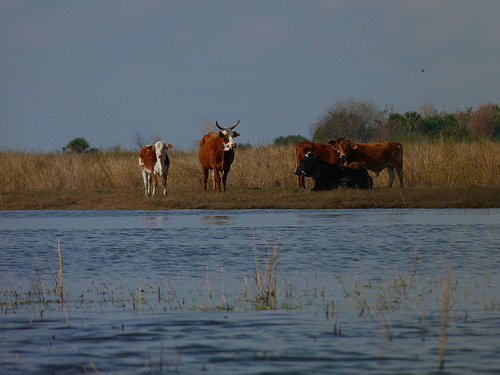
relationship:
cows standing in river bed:
[122, 112, 411, 196] [38, 175, 482, 206]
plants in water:
[130, 243, 465, 318] [35, 219, 462, 276]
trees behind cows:
[296, 93, 493, 149] [120, 111, 435, 207]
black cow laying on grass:
[296, 147, 375, 188] [13, 134, 498, 197]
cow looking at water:
[198, 120, 240, 189] [4, 210, 440, 371]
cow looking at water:
[137, 134, 196, 194] [4, 210, 440, 371]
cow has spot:
[198, 120, 240, 189] [218, 128, 228, 142]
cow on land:
[137, 134, 196, 194] [7, 141, 499, 203]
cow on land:
[198, 120, 240, 189] [7, 141, 499, 203]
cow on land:
[330, 131, 409, 199] [7, 141, 499, 203]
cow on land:
[279, 138, 339, 188] [7, 141, 499, 203]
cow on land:
[318, 165, 378, 193] [7, 141, 499, 203]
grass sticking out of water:
[4, 223, 495, 342] [20, 208, 483, 363]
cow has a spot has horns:
[196, 115, 250, 194] [214, 117, 242, 131]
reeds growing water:
[267, 130, 470, 184] [20, 239, 468, 361]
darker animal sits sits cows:
[295, 150, 376, 191] [293, 124, 417, 194]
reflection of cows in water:
[141, 204, 415, 237] [92, 201, 347, 244]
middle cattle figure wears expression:
[196, 118, 246, 193] [195, 119, 253, 168]